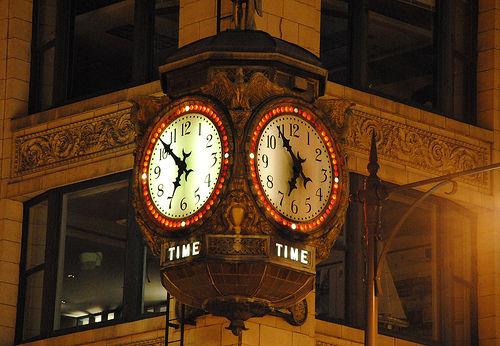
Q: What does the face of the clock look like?
A: White.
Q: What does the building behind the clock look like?
A: Brown with windows.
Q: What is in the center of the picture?
A: Round clock face with lights.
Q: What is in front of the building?
A: Multi-faced clock.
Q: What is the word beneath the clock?
A: Time.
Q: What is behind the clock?
A: A building.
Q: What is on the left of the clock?
A: A window.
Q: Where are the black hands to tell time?
A: On the clocks.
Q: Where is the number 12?
A: On the clock.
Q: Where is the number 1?
A: On the clock.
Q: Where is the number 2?
A: On the clock.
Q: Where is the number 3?
A: On the clock.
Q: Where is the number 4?
A: On the clock.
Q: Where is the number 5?
A: On the clock.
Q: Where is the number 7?
A: On the clock.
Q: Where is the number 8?
A: On the clock.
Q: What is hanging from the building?
A: A clock.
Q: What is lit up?
A: The clock.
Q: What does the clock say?
A: Time.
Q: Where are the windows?
A: On the building.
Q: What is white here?
A: The clock face.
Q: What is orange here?
A: A ring on the clock.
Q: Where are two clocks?
A: On the building.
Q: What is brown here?
A: The clock case.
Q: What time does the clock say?
A: 6:52.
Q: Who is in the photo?
A: No one.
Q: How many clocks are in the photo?
A: 2.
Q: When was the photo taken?
A: At night.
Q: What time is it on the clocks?
A: 6:51 p.m.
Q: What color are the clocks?
A: White.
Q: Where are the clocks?
A: On the wall.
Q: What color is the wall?
A: Brown.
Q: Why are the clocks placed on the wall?
A: For all to see the time.